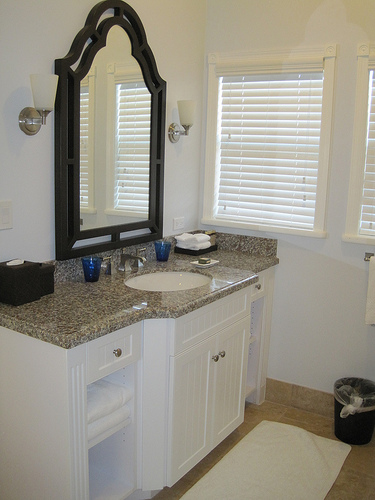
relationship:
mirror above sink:
[53, 1, 165, 260] [123, 267, 212, 292]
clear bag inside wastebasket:
[332, 376, 373, 420] [329, 374, 374, 449]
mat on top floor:
[175, 418, 349, 500] [148, 392, 374, 498]